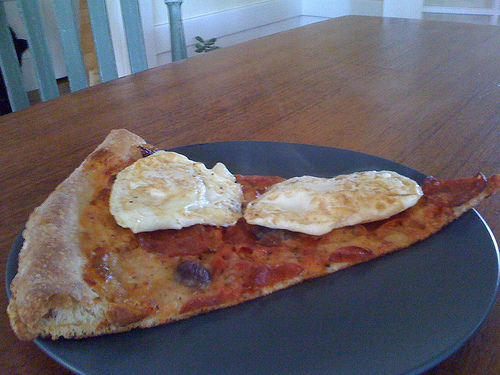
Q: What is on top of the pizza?
A: Eggs.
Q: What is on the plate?
A: Food.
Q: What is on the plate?
A: Pizza.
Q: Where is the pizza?
A: On the plate.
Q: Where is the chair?
A: At the table.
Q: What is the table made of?
A: Wood.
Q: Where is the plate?
A: On the table.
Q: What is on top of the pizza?
A: Eggs.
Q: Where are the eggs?
A: On top of the pizza.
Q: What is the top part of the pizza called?
A: Crust.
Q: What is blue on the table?
A: Plate.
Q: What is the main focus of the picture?
A: A pizza slice.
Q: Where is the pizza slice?
A: In grey plate.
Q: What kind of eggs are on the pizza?
A: Fried.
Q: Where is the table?
A: In the room.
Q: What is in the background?
A: Blue vertical objects.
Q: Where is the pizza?
A: On a plate.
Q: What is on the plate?
A: A pizza.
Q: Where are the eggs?
A: On the pizza.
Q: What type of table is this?
A: Wooden.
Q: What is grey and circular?
A: A plate.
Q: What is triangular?
A: The pizza.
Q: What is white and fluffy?
A: Eggs.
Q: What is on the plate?
A: A slice of pizza.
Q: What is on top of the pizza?
A: Eggs.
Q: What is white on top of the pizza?
A: Egg whites.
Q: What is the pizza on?
A: Plate.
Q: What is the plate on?
A: Table.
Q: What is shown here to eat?
A: Pizza.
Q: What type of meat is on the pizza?
A: Pepperoni.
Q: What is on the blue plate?
A: Pizza.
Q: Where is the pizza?
A: A blue plate.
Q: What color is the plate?
A: Blue.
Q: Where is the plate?
A: The table.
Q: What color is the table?
A: Brown.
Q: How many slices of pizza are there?
A: 1.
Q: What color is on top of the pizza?
A: White.